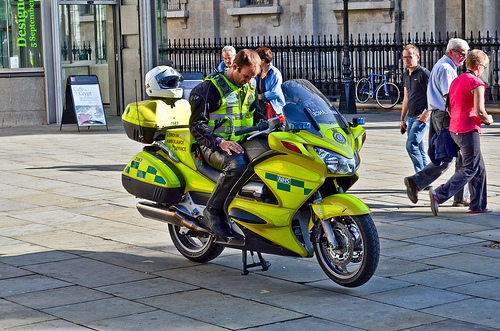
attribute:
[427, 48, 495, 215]
woman — walking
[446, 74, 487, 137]
shirt — red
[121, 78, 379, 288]
motorcycle — yellow, neon yellow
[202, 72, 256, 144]
vest — yellow, yellow reflector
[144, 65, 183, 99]
helmet — white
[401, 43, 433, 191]
man — walking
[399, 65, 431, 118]
shirt — black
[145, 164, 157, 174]
rectangle design — green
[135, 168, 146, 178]
rectangle design — green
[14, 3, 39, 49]
letters — green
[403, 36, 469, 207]
man — walking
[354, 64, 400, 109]
bike — blue, unattended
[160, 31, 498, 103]
gate — black, metal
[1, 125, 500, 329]
walkway — concrete blocks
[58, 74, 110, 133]
sign — advertising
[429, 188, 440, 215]
shoe — white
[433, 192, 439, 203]
stripes — red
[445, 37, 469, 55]
hair — gray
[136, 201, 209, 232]
muffler — chrome